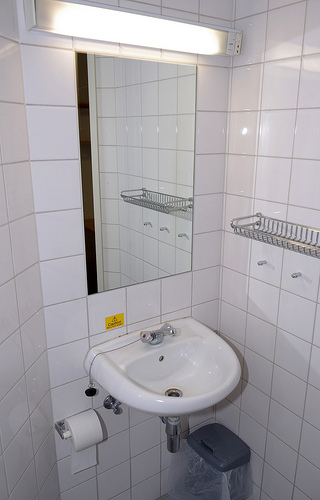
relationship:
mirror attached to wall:
[68, 48, 195, 297] [15, 0, 236, 490]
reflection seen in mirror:
[119, 185, 192, 216] [68, 48, 195, 297]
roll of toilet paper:
[62, 408, 101, 474] [64, 408, 104, 476]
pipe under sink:
[159, 412, 182, 452] [82, 313, 244, 414]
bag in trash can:
[166, 443, 253, 498] [183, 422, 250, 498]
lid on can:
[180, 420, 253, 473] [185, 421, 252, 500]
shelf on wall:
[230, 212, 319, 258] [0, 1, 320, 497]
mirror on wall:
[68, 48, 195, 297] [15, 0, 236, 490]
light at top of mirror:
[19, 3, 247, 62] [68, 48, 195, 297]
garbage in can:
[169, 422, 254, 499] [188, 420, 252, 473]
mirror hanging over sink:
[74, 48, 196, 297] [123, 333, 232, 401]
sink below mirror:
[123, 333, 232, 401] [74, 48, 196, 297]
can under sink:
[186, 441, 283, 493] [95, 310, 272, 438]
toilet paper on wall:
[56, 405, 111, 474] [15, 0, 236, 490]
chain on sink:
[87, 334, 154, 384] [94, 299, 232, 395]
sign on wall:
[103, 311, 126, 331] [15, 0, 236, 490]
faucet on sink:
[137, 316, 186, 355] [82, 313, 244, 414]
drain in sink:
[165, 386, 183, 400] [82, 313, 244, 414]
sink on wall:
[78, 318, 246, 424] [15, 0, 236, 490]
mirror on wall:
[68, 48, 195, 297] [0, 1, 320, 497]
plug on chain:
[81, 385, 99, 401] [101, 342, 127, 357]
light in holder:
[19, 3, 247, 62] [21, 2, 248, 63]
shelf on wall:
[230, 212, 319, 258] [196, 0, 315, 498]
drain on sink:
[163, 382, 184, 402] [87, 303, 249, 450]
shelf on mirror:
[220, 203, 319, 256] [68, 48, 195, 297]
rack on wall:
[227, 206, 316, 275] [235, 65, 314, 359]